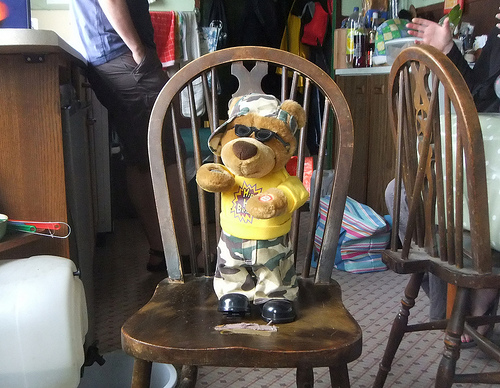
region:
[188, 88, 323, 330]
stuffed bear standing in chair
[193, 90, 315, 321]
toy bear with camouflaged pants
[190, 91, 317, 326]
toy bear with sunglasses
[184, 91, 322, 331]
toy bear with yellow shirt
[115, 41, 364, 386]
dark brown wooden chair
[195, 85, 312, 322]
the teddy bear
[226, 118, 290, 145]
the black sunglasses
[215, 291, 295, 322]
black shiny shoes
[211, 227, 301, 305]
army gear pants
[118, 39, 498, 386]
the wooden chairs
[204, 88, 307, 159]
the hat on head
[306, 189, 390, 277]
striped bag on floor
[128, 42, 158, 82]
hand in pocket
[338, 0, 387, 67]
bottles on counter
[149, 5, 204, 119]
towels on holder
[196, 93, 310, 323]
Teddy bear standing on a chair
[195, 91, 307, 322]
Teddy bear with sunglasses wearing a yellow shirt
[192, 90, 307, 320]
Teddy bear with black boots wearing a cap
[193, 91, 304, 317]
Standing teddy bear wearing camouflage pants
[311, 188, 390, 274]
Striped tote bag on the floor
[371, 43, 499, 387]
Wood chair next to a table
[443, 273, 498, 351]
Foot in sandal behind a chair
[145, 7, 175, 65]
Red towel hanging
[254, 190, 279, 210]
Red and white button on a teddy bear's hand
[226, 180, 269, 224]
Logo on a yellow shirt behind a teddy bear's hand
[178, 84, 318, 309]
a bear on a chair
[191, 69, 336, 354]
a teddy bear on a chair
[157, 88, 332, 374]
a bear standing on a chair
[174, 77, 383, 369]
a teddy bear standing on a chair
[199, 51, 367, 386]
a bear standing on a brown chair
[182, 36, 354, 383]
a teddy bear standing on a brown chair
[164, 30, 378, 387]
a wooden brown chair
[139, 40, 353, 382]
a chair that is brown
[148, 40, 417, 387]
a chair that is wooden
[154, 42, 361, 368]
a chair that is inside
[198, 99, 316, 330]
A stuffed bear standing on a chair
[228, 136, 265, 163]
A brown stuffed animal nose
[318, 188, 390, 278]
A multi-colored bag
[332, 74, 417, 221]
Two wooden cabinets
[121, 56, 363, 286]
A wooden chair back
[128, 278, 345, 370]
Wooden kitchen chair seat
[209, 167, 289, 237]
Small yellow stuffed animal shirt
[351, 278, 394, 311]
Section of gray patterned carpeting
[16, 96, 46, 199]
Section of woodgrain surface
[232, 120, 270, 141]
Toy plastic sunglasses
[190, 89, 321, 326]
Stuffed bear sunglasses camo attire.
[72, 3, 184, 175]
Person blue shirt black shorts leaning.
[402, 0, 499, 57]
Preson's hands explaining comments.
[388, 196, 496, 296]
Wood chair seat needs dusting.